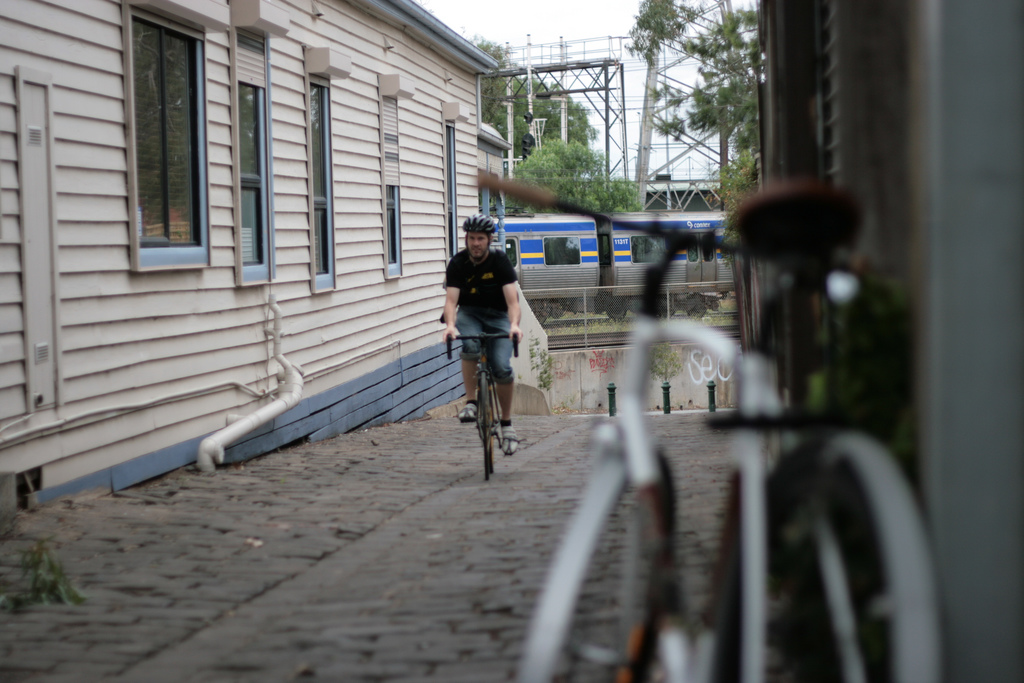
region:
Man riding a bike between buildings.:
[435, 220, 538, 480]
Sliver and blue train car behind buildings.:
[474, 208, 740, 322]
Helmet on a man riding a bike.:
[460, 212, 499, 235]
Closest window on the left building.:
[110, 4, 227, 281]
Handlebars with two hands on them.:
[441, 326, 524, 361]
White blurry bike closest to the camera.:
[476, 162, 948, 676]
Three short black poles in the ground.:
[593, 370, 727, 412]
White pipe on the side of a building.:
[193, 291, 323, 470]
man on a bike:
[322, 81, 690, 511]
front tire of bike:
[429, 369, 531, 512]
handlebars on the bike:
[398, 307, 544, 405]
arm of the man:
[495, 262, 544, 343]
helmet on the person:
[441, 187, 521, 249]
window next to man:
[245, 37, 386, 345]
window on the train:
[508, 202, 625, 289]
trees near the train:
[471, 60, 621, 225]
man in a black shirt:
[381, 167, 585, 382]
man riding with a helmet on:
[344, 168, 616, 501]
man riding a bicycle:
[441, 208, 528, 478]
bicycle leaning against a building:
[465, 162, 952, 678]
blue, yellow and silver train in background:
[492, 208, 740, 301]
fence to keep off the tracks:
[520, 276, 748, 349]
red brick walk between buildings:
[5, 407, 742, 679]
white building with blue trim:
[3, 0, 506, 525]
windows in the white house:
[123, 4, 459, 276]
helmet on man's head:
[460, 211, 500, 257]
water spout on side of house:
[196, 285, 305, 473]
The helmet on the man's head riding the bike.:
[461, 212, 496, 233]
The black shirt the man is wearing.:
[444, 252, 514, 317]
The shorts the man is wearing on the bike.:
[442, 310, 518, 378]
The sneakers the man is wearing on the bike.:
[453, 389, 530, 462]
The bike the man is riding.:
[439, 322, 525, 484]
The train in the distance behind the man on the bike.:
[470, 209, 755, 331]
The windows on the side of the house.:
[119, 37, 490, 309]